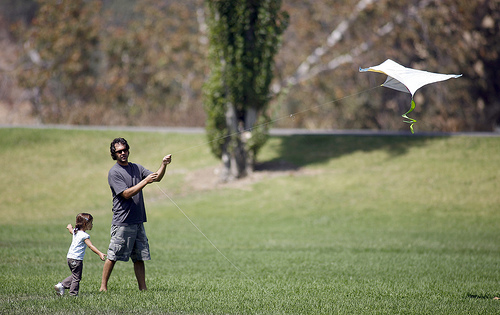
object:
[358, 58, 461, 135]
kite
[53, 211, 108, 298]
kid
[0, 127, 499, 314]
ground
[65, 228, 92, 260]
white shirt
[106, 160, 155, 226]
shirt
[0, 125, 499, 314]
patch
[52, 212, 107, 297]
girl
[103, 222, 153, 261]
shorts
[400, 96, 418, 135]
ribbon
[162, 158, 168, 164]
fingers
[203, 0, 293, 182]
tree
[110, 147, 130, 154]
sunglasses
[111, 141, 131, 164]
face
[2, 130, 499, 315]
grass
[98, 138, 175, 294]
man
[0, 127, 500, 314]
field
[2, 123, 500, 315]
park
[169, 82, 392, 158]
string